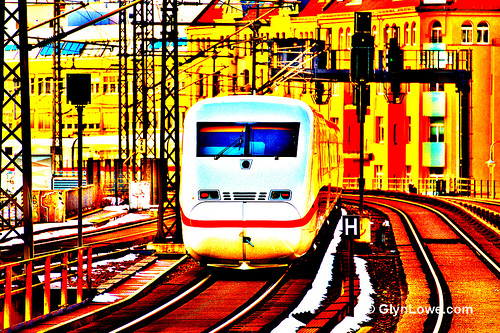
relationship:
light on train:
[266, 185, 294, 203] [178, 92, 346, 274]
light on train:
[196, 187, 220, 203] [178, 92, 346, 274]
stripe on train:
[178, 195, 319, 230] [48, 121, 319, 258]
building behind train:
[182, 0, 498, 195] [175, 95, 355, 263]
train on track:
[178, 92, 346, 274] [102, 265, 289, 330]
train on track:
[178, 92, 346, 274] [336, 192, 499, 331]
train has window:
[178, 92, 346, 274] [198, 122, 247, 154]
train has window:
[178, 92, 346, 274] [249, 122, 297, 154]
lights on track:
[306, 11, 406, 121] [40, 187, 495, 331]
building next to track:
[182, 0, 498, 195] [358, 183, 490, 330]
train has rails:
[178, 92, 346, 274] [101, 263, 292, 331]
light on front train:
[196, 187, 220, 203] [178, 92, 346, 274]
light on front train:
[266, 185, 294, 203] [178, 92, 346, 274]